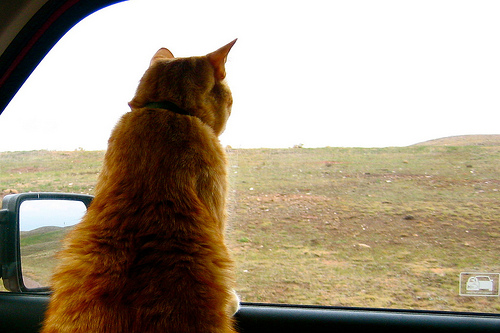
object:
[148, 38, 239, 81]
ears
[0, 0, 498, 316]
window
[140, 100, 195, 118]
ribbon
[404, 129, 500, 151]
hill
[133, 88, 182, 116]
animal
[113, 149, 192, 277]
cat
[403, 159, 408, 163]
animal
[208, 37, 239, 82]
ear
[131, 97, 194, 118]
collar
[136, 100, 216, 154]
neck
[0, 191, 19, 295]
sidemirror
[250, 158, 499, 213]
grass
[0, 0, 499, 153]
sky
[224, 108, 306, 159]
wall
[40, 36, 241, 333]
animal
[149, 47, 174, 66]
ear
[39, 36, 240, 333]
cat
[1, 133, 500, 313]
ground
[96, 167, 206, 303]
cat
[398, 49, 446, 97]
sky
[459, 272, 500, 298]
sticker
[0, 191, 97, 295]
mirror